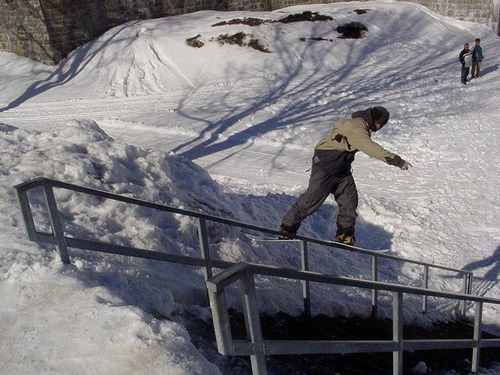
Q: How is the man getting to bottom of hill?
A: Top of rail.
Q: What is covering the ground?
A: Snow.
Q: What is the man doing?
A: Snowboarding.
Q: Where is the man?
A: On a rail.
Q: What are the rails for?
A: The stairs.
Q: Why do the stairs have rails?
A: For safety.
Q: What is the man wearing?
A: Coat.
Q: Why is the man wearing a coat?
A: To stay warm.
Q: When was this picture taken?
A: In the winter.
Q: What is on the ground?
A: Snow.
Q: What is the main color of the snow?
A: White.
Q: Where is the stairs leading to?
A: Down to the snow.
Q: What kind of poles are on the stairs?
A: Metal.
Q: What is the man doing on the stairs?
A: Snowboarding.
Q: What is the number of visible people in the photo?
A: 3.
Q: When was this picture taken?
A: Taken during the day.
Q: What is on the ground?
A: Shadows.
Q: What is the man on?
A: Skies.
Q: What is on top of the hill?
A: Rocks.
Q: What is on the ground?
A: Snow.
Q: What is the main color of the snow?
A: White.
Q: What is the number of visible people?
A: 3.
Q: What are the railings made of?
A: Iron.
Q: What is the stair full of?
A: Snow.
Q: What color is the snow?
A: White.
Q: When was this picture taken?
A: Daytime.